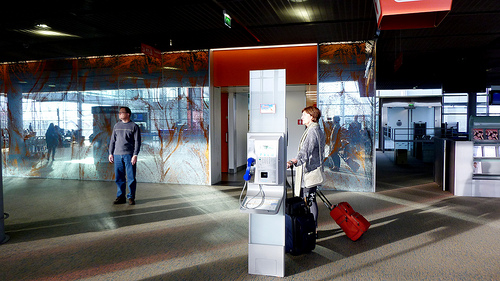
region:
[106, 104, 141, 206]
man in a gray sweater and blue jeans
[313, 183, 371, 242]
orange piece of luggage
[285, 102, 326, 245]
woman with short hair and white purse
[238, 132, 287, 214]
telephone mounted on the wall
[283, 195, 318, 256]
blue piece of luggage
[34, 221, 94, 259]
gray laminated floor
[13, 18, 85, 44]
light on the ceiling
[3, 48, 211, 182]
glass wall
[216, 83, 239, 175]
half-open orange door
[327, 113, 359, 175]
reflection of a person with a suitcase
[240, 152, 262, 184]
blue telephone handset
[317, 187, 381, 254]
red suitcase being pulled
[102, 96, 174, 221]
man standing, facing to his right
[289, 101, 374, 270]
woman pulling baggage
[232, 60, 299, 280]
telephone on stand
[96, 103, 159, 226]
man wearing blue jeans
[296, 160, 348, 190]
handbag on womans shoulder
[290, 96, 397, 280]
woman with two suitcases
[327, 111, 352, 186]
reflection of woman pulling suitcases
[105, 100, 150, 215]
man wearing glasses on face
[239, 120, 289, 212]
payphone with blue phone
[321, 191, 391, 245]
red rolling suitcase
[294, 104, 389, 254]
woman pulling a red suitcase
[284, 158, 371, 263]
two rolling suitcases with black handles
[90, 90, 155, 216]
man standing in blue jeans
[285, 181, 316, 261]
black suitcase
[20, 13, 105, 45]
an overhead ceiling light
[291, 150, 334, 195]
white purse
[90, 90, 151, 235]
man in a long sleeved shirt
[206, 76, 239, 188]
a red door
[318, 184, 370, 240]
Red luggage with a handle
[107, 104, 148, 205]
A man standing still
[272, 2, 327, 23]
A reflection on the ceiling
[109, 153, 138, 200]
A pair of demin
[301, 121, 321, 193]
A white purse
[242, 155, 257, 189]
A blue telephone part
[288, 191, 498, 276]
A shadow on the floor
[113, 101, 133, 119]
Black hair on a head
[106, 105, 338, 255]
Two people in a lobby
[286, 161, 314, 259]
A blue luggage carrier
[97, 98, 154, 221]
Person in a grey sweater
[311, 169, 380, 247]
Large red suitcase on wheels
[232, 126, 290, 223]
White pay phone with blue handle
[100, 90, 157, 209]
Person in blue jeans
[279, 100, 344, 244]
Woman in grey sweater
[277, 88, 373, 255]
Woman with red luggage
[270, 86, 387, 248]
Woman with white purse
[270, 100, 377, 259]
Woman with brown hair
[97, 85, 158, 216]
Man wearing glasses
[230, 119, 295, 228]
Large white pay phone